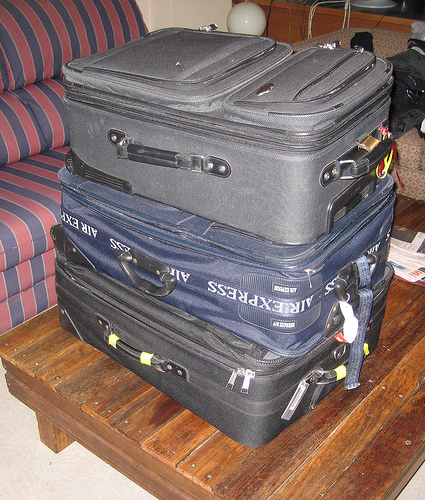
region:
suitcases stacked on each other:
[61, 51, 371, 351]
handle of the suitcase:
[308, 345, 367, 411]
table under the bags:
[301, 418, 357, 463]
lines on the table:
[113, 411, 204, 477]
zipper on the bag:
[210, 353, 264, 408]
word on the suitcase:
[193, 283, 324, 332]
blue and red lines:
[6, 94, 59, 160]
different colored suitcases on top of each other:
[85, 111, 326, 369]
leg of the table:
[30, 419, 77, 459]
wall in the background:
[168, 4, 188, 22]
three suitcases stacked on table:
[38, 63, 335, 454]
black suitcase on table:
[40, 208, 415, 434]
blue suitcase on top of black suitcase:
[52, 172, 421, 427]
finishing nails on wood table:
[27, 350, 212, 496]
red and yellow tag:
[363, 123, 411, 192]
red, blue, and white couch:
[1, 0, 166, 274]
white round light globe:
[223, 1, 282, 51]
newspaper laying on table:
[378, 198, 423, 320]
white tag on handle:
[322, 256, 362, 357]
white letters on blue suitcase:
[62, 204, 324, 318]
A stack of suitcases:
[57, 27, 395, 443]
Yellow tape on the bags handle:
[101, 331, 151, 367]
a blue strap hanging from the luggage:
[345, 258, 370, 392]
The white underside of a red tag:
[333, 298, 364, 345]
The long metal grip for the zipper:
[280, 377, 309, 433]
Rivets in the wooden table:
[0, 336, 71, 392]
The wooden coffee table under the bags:
[150, 442, 388, 496]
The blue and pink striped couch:
[2, 0, 49, 308]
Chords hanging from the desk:
[268, 0, 358, 28]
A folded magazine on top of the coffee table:
[393, 206, 423, 292]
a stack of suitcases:
[54, 26, 397, 447]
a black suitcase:
[52, 253, 391, 447]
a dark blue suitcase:
[57, 158, 396, 358]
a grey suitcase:
[63, 25, 390, 244]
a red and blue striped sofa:
[0, 0, 149, 338]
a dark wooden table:
[3, 282, 424, 498]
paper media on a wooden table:
[388, 223, 423, 286]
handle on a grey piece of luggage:
[104, 128, 230, 180]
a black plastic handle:
[114, 248, 176, 300]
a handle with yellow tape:
[92, 312, 187, 383]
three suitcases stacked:
[52, 26, 398, 430]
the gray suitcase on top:
[63, 34, 393, 238]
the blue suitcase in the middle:
[57, 167, 392, 351]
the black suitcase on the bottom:
[56, 253, 388, 448]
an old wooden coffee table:
[1, 194, 416, 498]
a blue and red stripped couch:
[3, 1, 147, 326]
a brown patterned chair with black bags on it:
[289, 29, 423, 200]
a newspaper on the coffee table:
[390, 227, 422, 284]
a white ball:
[227, 3, 267, 35]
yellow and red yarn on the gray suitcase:
[377, 144, 395, 182]